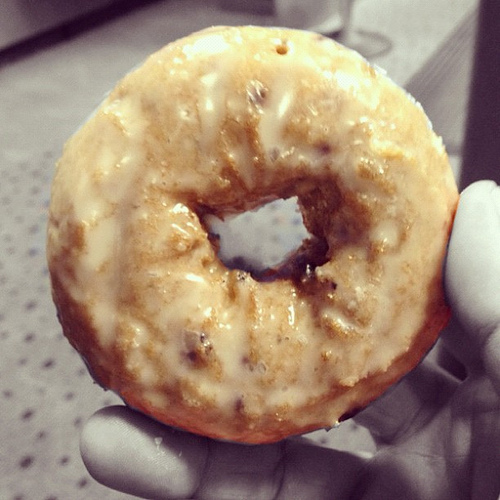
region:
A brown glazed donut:
[75, 73, 457, 439]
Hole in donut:
[195, 176, 349, 280]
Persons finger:
[76, 405, 391, 490]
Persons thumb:
[456, 187, 496, 317]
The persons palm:
[370, 447, 485, 498]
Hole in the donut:
[201, 158, 333, 295]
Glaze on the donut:
[223, 337, 240, 357]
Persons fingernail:
[486, 185, 498, 208]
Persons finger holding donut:
[365, 382, 450, 413]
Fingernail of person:
[482, 177, 495, 195]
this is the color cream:
[101, 301, 112, 326]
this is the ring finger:
[68, 397, 373, 495]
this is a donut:
[75, 212, 380, 447]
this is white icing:
[121, 277, 297, 383]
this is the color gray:
[49, 400, 74, 440]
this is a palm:
[406, 446, 464, 486]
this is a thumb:
[447, 189, 499, 370]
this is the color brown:
[170, 237, 182, 247]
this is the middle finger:
[350, 352, 490, 464]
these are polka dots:
[22, 325, 64, 440]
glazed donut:
[69, 46, 458, 491]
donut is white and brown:
[56, 64, 448, 434]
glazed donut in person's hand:
[103, 168, 493, 498]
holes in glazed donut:
[182, 29, 390, 400]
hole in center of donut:
[213, 157, 338, 311]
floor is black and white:
[13, 89, 83, 481]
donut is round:
[84, 60, 426, 442]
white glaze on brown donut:
[75, 90, 399, 403]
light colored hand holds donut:
[77, 368, 406, 498]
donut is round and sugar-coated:
[48, 25, 423, 435]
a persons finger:
[60, 358, 229, 498]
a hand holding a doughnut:
[74, 149, 498, 499]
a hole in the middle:
[172, 157, 359, 304]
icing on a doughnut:
[42, 170, 147, 360]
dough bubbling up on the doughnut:
[163, 315, 230, 371]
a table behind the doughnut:
[10, 370, 65, 485]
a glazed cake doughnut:
[19, 12, 476, 484]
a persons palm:
[351, 385, 494, 499]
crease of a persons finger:
[165, 432, 240, 499]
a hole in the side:
[242, 23, 330, 77]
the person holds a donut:
[53, 29, 461, 442]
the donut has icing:
[47, 29, 457, 441]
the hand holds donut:
[56, 23, 446, 443]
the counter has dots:
[0, 0, 481, 498]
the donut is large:
[46, 27, 457, 444]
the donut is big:
[51, 25, 455, 442]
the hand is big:
[83, 182, 498, 494]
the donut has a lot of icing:
[48, 27, 457, 444]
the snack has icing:
[45, 27, 457, 437]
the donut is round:
[51, 27, 453, 442]